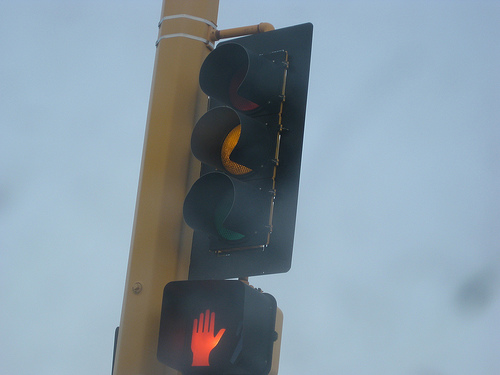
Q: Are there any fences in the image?
A: No, there are no fences.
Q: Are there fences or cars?
A: No, there are no fences or cars.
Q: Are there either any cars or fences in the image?
A: No, there are no fences or cars.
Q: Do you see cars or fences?
A: No, there are no fences or cars.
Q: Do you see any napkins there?
A: No, there are no napkins.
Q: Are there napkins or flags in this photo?
A: No, there are no napkins or flags.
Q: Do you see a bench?
A: No, there are no benches.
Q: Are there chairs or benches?
A: No, there are no benches or chairs.